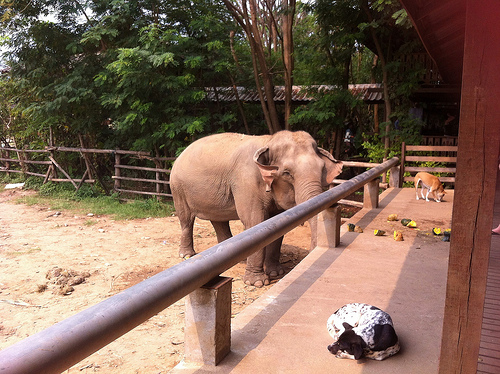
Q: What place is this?
A: It is a pen.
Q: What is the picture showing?
A: It is showing a pen.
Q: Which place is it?
A: It is a pen.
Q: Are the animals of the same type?
A: No, there are both dogs and elephants.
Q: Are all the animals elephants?
A: No, there are both dogs and elephants.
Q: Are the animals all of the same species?
A: No, there are both dogs and elephants.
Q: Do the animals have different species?
A: Yes, they are dogs and elephants.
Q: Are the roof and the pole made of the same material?
A: Yes, both the roof and the pole are made of metal.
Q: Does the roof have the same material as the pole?
A: Yes, both the roof and the pole are made of metal.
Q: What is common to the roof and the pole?
A: The material, both the roof and the pole are metallic.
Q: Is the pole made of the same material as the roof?
A: Yes, both the pole and the roof are made of metal.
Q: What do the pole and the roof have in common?
A: The material, both the pole and the roof are metallic.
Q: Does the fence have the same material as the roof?
A: No, the fence is made of wood and the roof is made of metal.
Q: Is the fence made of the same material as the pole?
A: No, the fence is made of wood and the pole is made of metal.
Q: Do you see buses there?
A: No, there are no buses.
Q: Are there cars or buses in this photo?
A: No, there are no buses or cars.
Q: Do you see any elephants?
A: Yes, there is an elephant.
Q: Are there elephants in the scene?
A: Yes, there is an elephant.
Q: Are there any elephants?
A: Yes, there is an elephant.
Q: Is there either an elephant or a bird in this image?
A: Yes, there is an elephant.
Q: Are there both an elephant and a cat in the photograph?
A: No, there is an elephant but no cats.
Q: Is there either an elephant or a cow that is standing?
A: Yes, the elephant is standing.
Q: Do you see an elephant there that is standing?
A: Yes, there is an elephant that is standing.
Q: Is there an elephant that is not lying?
A: Yes, there is an elephant that is standing.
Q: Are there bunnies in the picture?
A: No, there are no bunnies.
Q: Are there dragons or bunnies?
A: No, there are no bunnies or dragons.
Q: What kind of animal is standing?
A: The animal is an elephant.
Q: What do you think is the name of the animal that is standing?
A: The animal is an elephant.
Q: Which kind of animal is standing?
A: The animal is an elephant.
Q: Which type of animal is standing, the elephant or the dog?
A: The elephant is standing.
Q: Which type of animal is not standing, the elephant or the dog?
A: The dog is not standing.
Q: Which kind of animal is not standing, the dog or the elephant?
A: The dog is not standing.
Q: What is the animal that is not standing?
A: The animal is a dog.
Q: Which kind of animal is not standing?
A: The animal is a dog.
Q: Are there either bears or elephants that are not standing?
A: No, there is an elephant but it is standing.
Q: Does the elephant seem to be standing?
A: Yes, the elephant is standing.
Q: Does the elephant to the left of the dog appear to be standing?
A: Yes, the elephant is standing.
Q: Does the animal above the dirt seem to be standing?
A: Yes, the elephant is standing.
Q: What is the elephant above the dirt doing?
A: The elephant is standing.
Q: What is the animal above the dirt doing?
A: The elephant is standing.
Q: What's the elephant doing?
A: The elephant is standing.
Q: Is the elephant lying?
A: No, the elephant is standing.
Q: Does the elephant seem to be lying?
A: No, the elephant is standing.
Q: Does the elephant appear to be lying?
A: No, the elephant is standing.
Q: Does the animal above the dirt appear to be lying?
A: No, the elephant is standing.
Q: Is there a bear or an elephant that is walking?
A: No, there is an elephant but it is standing.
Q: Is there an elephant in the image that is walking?
A: No, there is an elephant but it is standing.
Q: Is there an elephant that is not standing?
A: No, there is an elephant but it is standing.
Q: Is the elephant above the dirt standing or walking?
A: The elephant is standing.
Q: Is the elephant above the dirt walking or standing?
A: The elephant is standing.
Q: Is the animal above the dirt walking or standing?
A: The elephant is standing.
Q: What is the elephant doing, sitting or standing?
A: The elephant is standing.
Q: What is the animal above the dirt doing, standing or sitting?
A: The elephant is standing.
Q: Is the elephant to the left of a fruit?
A: Yes, the elephant is to the left of a fruit.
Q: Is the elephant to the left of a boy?
A: No, the elephant is to the left of a fruit.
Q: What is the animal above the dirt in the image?
A: The animal is an elephant.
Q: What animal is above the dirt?
A: The animal is an elephant.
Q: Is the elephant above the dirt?
A: Yes, the elephant is above the dirt.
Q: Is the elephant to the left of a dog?
A: Yes, the elephant is to the left of a dog.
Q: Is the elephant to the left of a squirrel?
A: No, the elephant is to the left of a dog.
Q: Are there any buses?
A: No, there are no buses.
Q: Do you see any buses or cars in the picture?
A: No, there are no buses or cars.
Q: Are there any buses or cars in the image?
A: No, there are no buses or cars.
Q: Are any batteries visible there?
A: No, there are no batteries.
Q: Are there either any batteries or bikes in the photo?
A: No, there are no batteries or bikes.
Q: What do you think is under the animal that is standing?
A: The dirt is under the elephant.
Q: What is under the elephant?
A: The dirt is under the elephant.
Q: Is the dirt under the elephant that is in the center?
A: Yes, the dirt is under the elephant.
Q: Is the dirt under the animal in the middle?
A: Yes, the dirt is under the elephant.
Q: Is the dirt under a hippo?
A: No, the dirt is under the elephant.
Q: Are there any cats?
A: No, there are no cats.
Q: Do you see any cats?
A: No, there are no cats.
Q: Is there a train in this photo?
A: No, there are no trains.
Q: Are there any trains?
A: No, there are no trains.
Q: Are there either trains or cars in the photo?
A: No, there are no trains or cars.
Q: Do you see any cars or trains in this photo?
A: No, there are no trains or cars.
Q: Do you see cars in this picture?
A: No, there are no cars.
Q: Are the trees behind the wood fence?
A: Yes, the trees are behind the fence.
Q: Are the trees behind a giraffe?
A: No, the trees are behind the fence.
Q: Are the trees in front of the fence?
A: No, the trees are behind the fence.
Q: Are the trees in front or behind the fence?
A: The trees are behind the fence.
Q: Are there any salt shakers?
A: No, there are no salt shakers.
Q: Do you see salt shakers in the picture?
A: No, there are no salt shakers.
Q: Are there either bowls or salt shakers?
A: No, there are no salt shakers or bowls.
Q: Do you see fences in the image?
A: Yes, there is a fence.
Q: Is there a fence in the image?
A: Yes, there is a fence.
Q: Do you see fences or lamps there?
A: Yes, there is a fence.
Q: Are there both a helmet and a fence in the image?
A: No, there is a fence but no helmets.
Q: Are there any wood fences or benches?
A: Yes, there is a wood fence.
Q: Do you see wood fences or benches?
A: Yes, there is a wood fence.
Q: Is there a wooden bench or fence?
A: Yes, there is a wood fence.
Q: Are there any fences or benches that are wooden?
A: Yes, the fence is wooden.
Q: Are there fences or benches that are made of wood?
A: Yes, the fence is made of wood.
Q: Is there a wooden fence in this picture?
A: Yes, there is a wood fence.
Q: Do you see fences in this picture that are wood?
A: Yes, there is a wood fence.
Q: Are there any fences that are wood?
A: Yes, there is a wood fence.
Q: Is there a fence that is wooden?
A: Yes, there is a fence that is wooden.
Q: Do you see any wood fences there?
A: Yes, there is a fence that is made of wood.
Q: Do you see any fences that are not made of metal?
A: Yes, there is a fence that is made of wood.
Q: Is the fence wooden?
A: Yes, the fence is wooden.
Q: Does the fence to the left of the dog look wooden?
A: Yes, the fence is wooden.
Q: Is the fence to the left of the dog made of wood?
A: Yes, the fence is made of wood.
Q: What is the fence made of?
A: The fence is made of wood.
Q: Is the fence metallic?
A: No, the fence is wooden.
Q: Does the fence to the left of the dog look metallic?
A: No, the fence is wooden.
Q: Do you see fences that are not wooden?
A: No, there is a fence but it is wooden.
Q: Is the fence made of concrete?
A: No, the fence is made of wood.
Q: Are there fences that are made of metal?
A: No, there is a fence but it is made of wood.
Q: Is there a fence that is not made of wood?
A: No, there is a fence but it is made of wood.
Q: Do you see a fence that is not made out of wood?
A: No, there is a fence but it is made of wood.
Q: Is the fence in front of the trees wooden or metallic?
A: The fence is wooden.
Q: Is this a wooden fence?
A: Yes, this is a wooden fence.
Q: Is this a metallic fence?
A: No, this is a wooden fence.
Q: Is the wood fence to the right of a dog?
A: No, the fence is to the left of a dog.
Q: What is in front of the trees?
A: The fence is in front of the trees.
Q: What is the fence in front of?
A: The fence is in front of the trees.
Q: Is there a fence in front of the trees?
A: Yes, there is a fence in front of the trees.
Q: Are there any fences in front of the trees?
A: Yes, there is a fence in front of the trees.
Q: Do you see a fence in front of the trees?
A: Yes, there is a fence in front of the trees.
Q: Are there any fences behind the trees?
A: No, the fence is in front of the trees.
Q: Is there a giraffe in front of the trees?
A: No, there is a fence in front of the trees.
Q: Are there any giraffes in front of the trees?
A: No, there is a fence in front of the trees.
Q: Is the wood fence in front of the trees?
A: Yes, the fence is in front of the trees.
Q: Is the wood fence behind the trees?
A: No, the fence is in front of the trees.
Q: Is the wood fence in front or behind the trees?
A: The fence is in front of the trees.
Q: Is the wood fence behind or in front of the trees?
A: The fence is in front of the trees.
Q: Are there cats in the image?
A: No, there are no cats.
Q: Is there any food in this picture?
A: Yes, there is food.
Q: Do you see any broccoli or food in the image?
A: Yes, there is food.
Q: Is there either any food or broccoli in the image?
A: Yes, there is food.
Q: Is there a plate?
A: No, there are no plates.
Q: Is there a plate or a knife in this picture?
A: No, there are no plates or knives.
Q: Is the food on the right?
A: Yes, the food is on the right of the image.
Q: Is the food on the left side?
A: No, the food is on the right of the image.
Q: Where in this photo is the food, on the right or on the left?
A: The food is on the right of the image.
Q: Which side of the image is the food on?
A: The food is on the right of the image.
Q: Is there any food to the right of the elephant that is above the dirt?
A: Yes, there is food to the right of the elephant.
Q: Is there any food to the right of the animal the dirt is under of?
A: Yes, there is food to the right of the elephant.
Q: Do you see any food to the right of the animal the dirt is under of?
A: Yes, there is food to the right of the elephant.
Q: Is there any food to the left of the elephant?
A: No, the food is to the right of the elephant.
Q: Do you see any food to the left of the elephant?
A: No, the food is to the right of the elephant.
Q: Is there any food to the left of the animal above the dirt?
A: No, the food is to the right of the elephant.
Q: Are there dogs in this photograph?
A: Yes, there is a dog.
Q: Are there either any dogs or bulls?
A: Yes, there is a dog.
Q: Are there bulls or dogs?
A: Yes, there is a dog.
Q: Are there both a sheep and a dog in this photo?
A: No, there is a dog but no sheep.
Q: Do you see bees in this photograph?
A: No, there are no bees.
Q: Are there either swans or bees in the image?
A: No, there are no bees or swans.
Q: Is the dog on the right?
A: Yes, the dog is on the right of the image.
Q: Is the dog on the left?
A: No, the dog is on the right of the image.